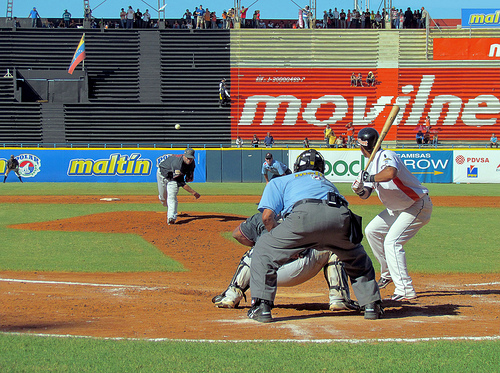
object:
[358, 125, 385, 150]
helmet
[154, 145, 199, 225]
pitcher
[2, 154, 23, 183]
outfielder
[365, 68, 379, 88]
fan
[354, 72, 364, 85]
fan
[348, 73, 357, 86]
fan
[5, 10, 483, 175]
bleachers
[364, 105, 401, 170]
bat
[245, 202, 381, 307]
pant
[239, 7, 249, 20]
shirt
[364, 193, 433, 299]
pants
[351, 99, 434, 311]
man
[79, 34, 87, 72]
pole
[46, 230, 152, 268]
grass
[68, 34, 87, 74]
flag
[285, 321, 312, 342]
chalk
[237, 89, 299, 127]
letter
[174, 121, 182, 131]
ball